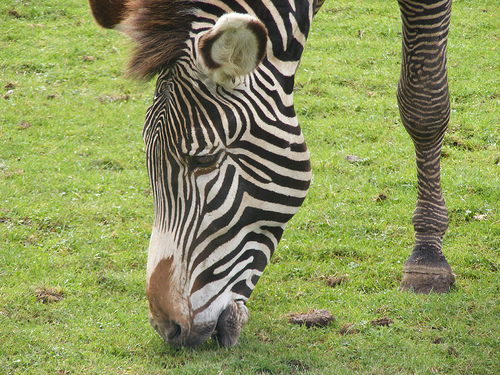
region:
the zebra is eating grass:
[71, 0, 461, 360]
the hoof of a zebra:
[390, 245, 465, 295]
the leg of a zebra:
[390, 0, 452, 290]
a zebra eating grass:
[78, 0, 332, 357]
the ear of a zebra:
[192, 11, 267, 83]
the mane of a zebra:
[130, 0, 191, 82]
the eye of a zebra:
[191, 150, 221, 171]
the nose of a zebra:
[155, 305, 201, 341]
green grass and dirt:
[4, 230, 135, 364]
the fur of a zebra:
[247, 150, 288, 202]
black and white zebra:
[101, 12, 312, 334]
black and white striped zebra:
[115, 12, 301, 344]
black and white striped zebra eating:
[119, 9, 305, 333]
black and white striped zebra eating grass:
[106, 15, 327, 341]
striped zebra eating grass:
[73, 7, 325, 353]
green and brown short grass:
[14, 32, 71, 97]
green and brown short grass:
[38, 120, 117, 172]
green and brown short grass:
[6, 169, 96, 244]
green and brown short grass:
[38, 247, 128, 332]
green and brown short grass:
[321, 235, 378, 312]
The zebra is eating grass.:
[20, 2, 465, 372]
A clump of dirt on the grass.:
[282, 303, 332, 329]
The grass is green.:
[35, 121, 97, 239]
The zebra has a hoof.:
[396, 266, 457, 296]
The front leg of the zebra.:
[381, 0, 467, 298]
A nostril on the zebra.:
[163, 318, 183, 344]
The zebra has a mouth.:
[200, 302, 241, 347]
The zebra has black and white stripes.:
[211, 175, 271, 243]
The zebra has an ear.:
[193, 12, 273, 87]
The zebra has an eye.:
[182, 136, 224, 174]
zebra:
[124, 9, 321, 342]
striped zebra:
[127, 19, 314, 341]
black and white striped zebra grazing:
[123, 2, 328, 352]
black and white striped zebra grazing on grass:
[99, 10, 304, 356]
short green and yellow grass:
[8, 276, 135, 340]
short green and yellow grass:
[11, 168, 123, 264]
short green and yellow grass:
[31, 82, 138, 173]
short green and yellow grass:
[314, 195, 374, 303]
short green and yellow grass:
[324, 48, 379, 133]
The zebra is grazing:
[74, 9, 457, 342]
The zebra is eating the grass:
[86, 9, 464, 349]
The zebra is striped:
[93, 8, 467, 358]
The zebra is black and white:
[83, 3, 467, 326]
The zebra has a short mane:
[108, 1, 218, 86]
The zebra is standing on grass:
[87, 5, 463, 372]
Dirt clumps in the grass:
[282, 294, 369, 344]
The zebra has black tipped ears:
[83, 4, 175, 49]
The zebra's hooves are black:
[363, 252, 462, 307]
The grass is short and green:
[17, 9, 489, 366]